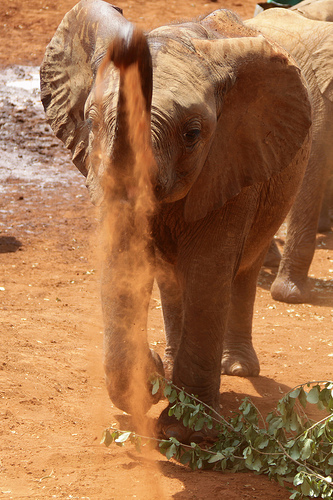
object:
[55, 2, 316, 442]
baby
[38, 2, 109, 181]
ear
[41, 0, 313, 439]
elephant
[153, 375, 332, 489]
grass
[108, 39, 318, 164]
head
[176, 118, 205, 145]
eye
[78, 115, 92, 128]
eyelashes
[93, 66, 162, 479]
dirt cloud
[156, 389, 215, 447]
feet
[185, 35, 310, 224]
left ear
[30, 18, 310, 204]
brown napkin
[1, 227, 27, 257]
shadow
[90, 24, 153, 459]
dust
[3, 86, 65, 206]
dirt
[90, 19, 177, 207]
trunk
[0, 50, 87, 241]
mud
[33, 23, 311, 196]
people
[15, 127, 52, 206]
ground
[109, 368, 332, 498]
shadow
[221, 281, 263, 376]
leg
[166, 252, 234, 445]
leg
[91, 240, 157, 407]
leg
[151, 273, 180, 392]
leg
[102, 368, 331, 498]
branches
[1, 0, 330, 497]
ground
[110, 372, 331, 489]
leaves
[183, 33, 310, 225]
ear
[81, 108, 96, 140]
eyes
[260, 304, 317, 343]
stones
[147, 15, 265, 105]
back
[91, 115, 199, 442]
soil